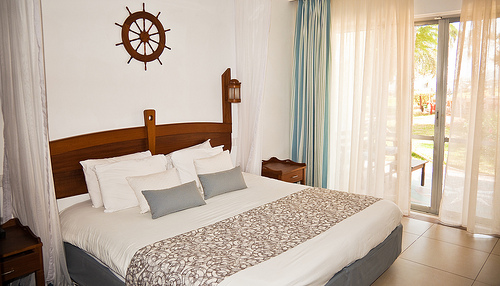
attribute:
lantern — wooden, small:
[225, 76, 242, 102]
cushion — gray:
[143, 181, 209, 219]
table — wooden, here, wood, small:
[2, 214, 47, 284]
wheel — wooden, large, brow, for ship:
[114, 3, 173, 70]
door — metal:
[346, 15, 498, 230]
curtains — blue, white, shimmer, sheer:
[294, 1, 413, 217]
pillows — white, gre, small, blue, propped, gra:
[78, 139, 249, 213]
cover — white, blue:
[50, 161, 401, 285]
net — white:
[235, 0, 259, 176]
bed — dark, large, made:
[47, 69, 410, 282]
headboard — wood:
[44, 67, 237, 196]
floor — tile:
[310, 181, 500, 285]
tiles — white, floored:
[375, 207, 499, 283]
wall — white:
[41, 4, 248, 199]